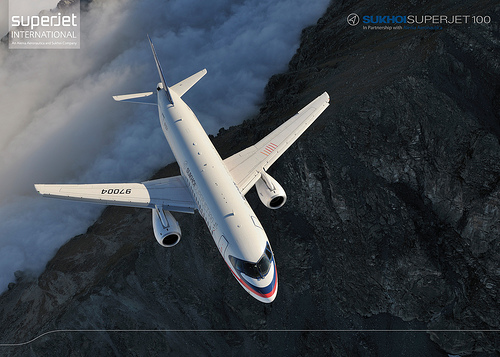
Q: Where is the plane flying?
A: Over a waterfall.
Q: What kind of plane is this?
A: Passenger plane.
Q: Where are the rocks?
A: Under the plane.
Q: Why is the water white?
A: Rushing.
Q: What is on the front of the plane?
A: Red and blue stripes.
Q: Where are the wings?
A: On either side of the plane.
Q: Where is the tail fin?
A: Back of the plane.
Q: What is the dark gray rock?
A: A cliff.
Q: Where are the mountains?
A: Below the jet.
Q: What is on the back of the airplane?
A: A tail.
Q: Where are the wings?
A: On the side of the airplane.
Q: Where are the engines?
A: Under the wings.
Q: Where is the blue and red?
A: The nose of the airplane.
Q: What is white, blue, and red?
A: The airplane.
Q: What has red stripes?
A: The airplane's wings.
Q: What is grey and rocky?
A: The mountainside.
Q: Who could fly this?
A: A pilot.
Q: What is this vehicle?
A: An airplane.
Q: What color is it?
A: White.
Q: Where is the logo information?
A: Top right corner.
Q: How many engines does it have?
A: Two.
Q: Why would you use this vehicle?
A: To fly from one place to another.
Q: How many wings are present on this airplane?
A: Two.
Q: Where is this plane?
A: In the sky.